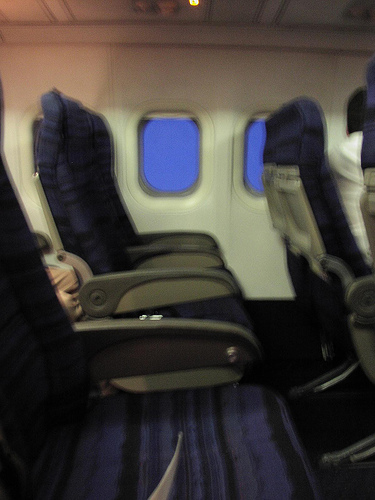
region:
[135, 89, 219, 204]
Window in an airplane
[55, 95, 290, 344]
Empty row of seats on an airplane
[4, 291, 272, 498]
An empty seat on an airplane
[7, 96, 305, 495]
Vacant seats on an airplane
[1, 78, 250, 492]
Empty airplane seats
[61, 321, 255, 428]
Arm rest of an airplane seat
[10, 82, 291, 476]
Two aisle seats and a window seat in an airplane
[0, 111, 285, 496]
Blue airplane seats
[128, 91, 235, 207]
An airplane window with the shutter up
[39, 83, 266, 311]
Airplane seats in the upright position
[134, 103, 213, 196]
small window on the airplane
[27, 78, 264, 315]
empty row of seats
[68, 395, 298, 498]
black and blue stripes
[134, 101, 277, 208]
two airplane windows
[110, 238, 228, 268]
armrest is down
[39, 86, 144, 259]
blue cushions on the seats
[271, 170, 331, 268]
tray table on the back of the seat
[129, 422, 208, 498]
srap of the seatbelt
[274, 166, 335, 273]
tray table is up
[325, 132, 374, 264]
thin white pillow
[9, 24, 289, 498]
a row of seats inside of an airplane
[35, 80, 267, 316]
two blue seats next to an airplane window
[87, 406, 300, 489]
the fabric of the airplane seat is a blue and black striped pattern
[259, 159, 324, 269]
fold up trays on the back of the seats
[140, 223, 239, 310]
arm rests attached to the seats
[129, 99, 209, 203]
airplane window looking out on the sky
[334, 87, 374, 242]
airplane passenger wearing a white shirt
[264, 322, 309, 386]
dark colored carpet covering the floor of the airplane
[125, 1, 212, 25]
light and signs above the seat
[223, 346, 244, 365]
button to recline the airplane seat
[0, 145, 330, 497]
THE SEAT IS BLACK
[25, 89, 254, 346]
THIS IS A SEAT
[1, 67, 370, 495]
MANY SEATS ON A PLANE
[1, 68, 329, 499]
THE SEATS ARE EMPTY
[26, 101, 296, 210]
THE WINDOWS ARE IN A ROW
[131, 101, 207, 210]
THE PLANE HAS A WINDOW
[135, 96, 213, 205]
THE WINDOW IS BLUE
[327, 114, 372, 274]
THE PERSON IS WEARING A WHITE SHIRT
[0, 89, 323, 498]
THE SEATS ARE GREY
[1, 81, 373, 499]
THE SEATS HAVE STRIPES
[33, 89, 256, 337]
Tall plush airline seat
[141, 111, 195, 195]
blue sky outside plane window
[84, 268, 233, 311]
grey plastic armrest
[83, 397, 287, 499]
blue and black patterned fabric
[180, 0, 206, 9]
small orange light on ceiling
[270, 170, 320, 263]
collapsible tray on back of seat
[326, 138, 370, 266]
large white pillow on seat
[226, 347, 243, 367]
small silver button in armrest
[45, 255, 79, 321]
pair of khaki pants and mans knees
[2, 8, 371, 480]
Inside of a passenger plane cabin